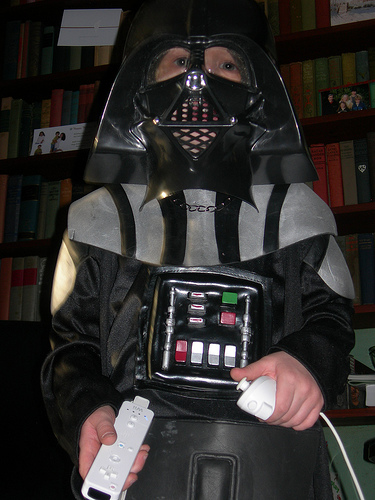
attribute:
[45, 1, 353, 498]
boy — smiling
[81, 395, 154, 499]
controller — white, wii remote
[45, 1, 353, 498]
costume — black, gray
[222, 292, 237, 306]
buttons — green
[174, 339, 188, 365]
switch — red, white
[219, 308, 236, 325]
buttons — red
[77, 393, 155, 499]
nunchuck — white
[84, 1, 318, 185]
helmet — black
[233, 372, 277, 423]
remote — white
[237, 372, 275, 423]
joystick — nunchuck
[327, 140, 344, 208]
book — orange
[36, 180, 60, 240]
book — grey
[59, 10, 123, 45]
paper — hanging